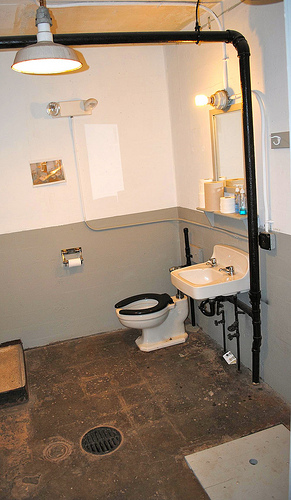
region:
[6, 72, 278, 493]
An incomplete bathroom.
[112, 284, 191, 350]
A commercial toilet with a black seat.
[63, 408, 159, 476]
A drain in the center of the room.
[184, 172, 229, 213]
Paper towels and toilet paper.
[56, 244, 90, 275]
Toilet paper on the toilet paper holder.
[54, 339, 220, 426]
A cement floor.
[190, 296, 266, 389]
Black piping.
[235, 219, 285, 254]
A light switch.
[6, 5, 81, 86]
A lamp hanging from the ceiling.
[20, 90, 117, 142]
Emergency lights attached to the wall.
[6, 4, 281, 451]
a non classy bathroom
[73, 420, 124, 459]
a metal drain hole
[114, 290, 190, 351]
a white and black toilet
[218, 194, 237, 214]
a roll of toilet paper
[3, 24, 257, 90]
black round tubing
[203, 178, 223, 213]
a roll of brown paper towels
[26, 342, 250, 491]
a floor with no tile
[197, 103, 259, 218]
a mirror hanging on the wall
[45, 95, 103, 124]
two lights that are not on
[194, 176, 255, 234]
a shelf with supplies on it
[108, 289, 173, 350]
A toilet with a black seat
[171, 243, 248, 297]
A white sink with faucets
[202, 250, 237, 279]
Faucet fixtures on a sink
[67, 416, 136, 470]
A drain in a floor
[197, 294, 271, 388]
Piping in a bathroom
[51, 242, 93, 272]
A toilet paper holder on a wall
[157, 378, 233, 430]
A patch of dirty tiles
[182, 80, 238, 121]
A light bulb above a mirror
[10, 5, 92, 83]
An overhead lamp in a bathroom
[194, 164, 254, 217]
Toiletry items in front of a mirror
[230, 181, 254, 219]
almost empty pump soap dispenser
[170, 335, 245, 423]
very dirty concrete flooring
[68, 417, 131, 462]
drain in middle of floor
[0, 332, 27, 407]
black litter box in bathroom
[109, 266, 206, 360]
toilet with black seat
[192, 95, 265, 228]
white framed mirror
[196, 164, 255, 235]
extra supplies on shelf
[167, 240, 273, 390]
black pipes under sink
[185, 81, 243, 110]
light fixture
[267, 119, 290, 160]
white hook to hang things on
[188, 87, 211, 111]
Light bulb above the sink.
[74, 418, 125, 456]
Circular shaped drain on the floor.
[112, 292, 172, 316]
Black toilet seat on toilet.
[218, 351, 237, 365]
White piece of paper below sink.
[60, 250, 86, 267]
Toilet paper roll mounted on the wall.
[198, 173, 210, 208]
Two toilet paper rolls stacked on shelf.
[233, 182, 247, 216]
Soap dispenser bottle on shelf above sink.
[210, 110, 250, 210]
Mirror above sink and shelf.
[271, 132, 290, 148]
White hook mounted on wooden plaque on wall.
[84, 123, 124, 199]
White paint mark on wall to the left of the toilet.